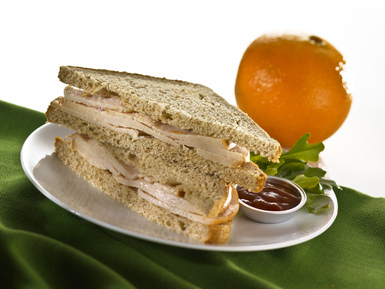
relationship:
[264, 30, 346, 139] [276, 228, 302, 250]
orange on plate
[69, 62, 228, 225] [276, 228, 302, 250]
sandwhich on plate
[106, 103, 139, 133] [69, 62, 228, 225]
meat in sandwhich